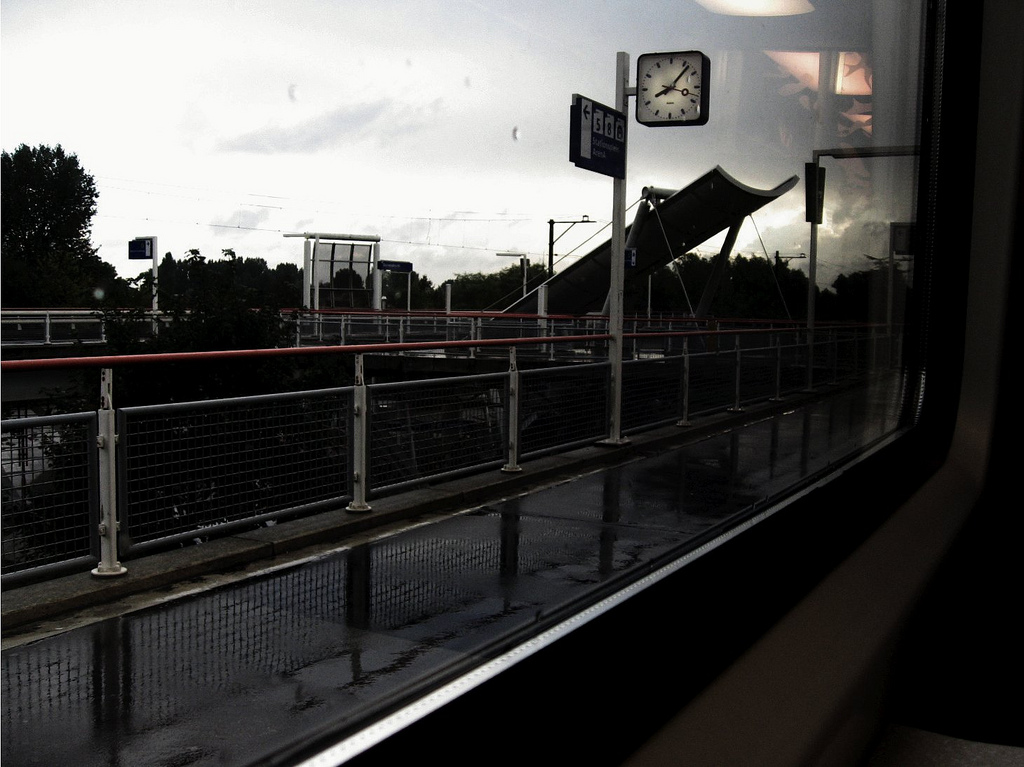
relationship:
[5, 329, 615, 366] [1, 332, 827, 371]
top of railing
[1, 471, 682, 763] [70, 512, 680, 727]
reflection in water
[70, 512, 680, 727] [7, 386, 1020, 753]
water on ground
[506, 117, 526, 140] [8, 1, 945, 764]
drop on window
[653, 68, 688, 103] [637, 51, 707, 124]
hands on clock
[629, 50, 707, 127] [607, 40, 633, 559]
clock on pole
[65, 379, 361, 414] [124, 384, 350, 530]
rail on fence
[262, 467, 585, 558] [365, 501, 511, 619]
rail on fence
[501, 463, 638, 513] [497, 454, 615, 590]
rail on fence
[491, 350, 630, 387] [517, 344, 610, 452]
rail on fence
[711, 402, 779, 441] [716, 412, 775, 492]
rail on fence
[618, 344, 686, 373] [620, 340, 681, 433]
rail on fence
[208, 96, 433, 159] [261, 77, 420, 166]
clouds in sky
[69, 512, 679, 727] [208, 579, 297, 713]
water on ground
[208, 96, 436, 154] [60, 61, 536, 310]
clouds in sky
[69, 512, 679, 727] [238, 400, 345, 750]
water on pavement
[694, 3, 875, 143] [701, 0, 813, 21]
reflection of light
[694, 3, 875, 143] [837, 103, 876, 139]
reflection of light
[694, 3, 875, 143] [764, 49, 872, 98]
reflection of light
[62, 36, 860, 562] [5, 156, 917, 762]
scene of a train station